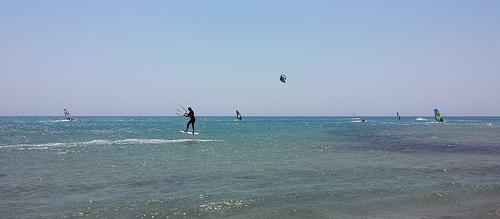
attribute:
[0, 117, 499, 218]
water — ocean, blue, calm, white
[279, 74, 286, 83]
kite — dark, small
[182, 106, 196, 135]
man — person, running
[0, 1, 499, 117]
sky — blue, hazy, gray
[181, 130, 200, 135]
kiteboard — white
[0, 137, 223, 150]
wave — small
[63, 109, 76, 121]
boat — sail boat, speeding, small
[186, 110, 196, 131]
wetsuit — black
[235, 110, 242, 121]
boat — white, red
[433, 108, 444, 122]
boat — blue, yellow, white